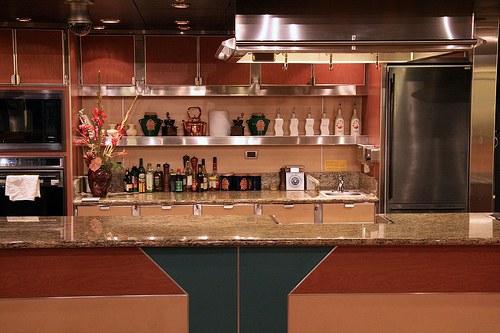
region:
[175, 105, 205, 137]
Gold teapot on shelf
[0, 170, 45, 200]
white kitchen towel on oven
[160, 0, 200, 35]
recessed lighting in ceiling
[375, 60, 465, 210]
stainless steel refridgerator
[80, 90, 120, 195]
vase full of flowers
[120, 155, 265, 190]
condiments lined up on counter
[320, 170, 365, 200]
silver kitchen sink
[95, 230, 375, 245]
reflection of light on counter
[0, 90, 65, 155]
black kitchen appliance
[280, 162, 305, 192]
white food scale on counter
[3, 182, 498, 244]
A light brown marble countertop.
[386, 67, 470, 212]
A silver refrigerator.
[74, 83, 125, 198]
Red flowers on the countertop.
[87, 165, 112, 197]
A brown flower vase.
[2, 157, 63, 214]
A silver and black oven.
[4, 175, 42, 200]
A white dish cloth.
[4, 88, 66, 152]
A silver and black microwave.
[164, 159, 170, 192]
A brown pepper grinder.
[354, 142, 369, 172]
A silver box on the wall with a paper towel hanging out of it.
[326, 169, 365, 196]
A small sink.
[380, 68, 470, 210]
refrigerator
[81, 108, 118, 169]
flowers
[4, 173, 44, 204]
a cloth on the oven door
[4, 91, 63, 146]
the microwave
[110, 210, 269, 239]
a marble counter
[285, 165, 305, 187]
a white food scale on the counter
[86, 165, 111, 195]
a vase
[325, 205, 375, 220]
drawers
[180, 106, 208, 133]
a brown tea kettle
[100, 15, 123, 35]
a light on the ceiling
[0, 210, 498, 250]
tan-colored kitchen island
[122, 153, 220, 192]
variety of cooking sauces and spices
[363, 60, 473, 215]
stainless steel refrigerator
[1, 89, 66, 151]
black microwave mounted on wall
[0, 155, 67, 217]
black oven with a white towel hanging from it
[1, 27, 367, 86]
cherrywood-colored upper kitchen cabinets with steel trim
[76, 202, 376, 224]
cream color drawers with steel trim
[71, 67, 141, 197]
red flowers in a ceramic vase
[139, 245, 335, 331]
blue front of kitchen island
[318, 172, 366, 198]
small kitchen sink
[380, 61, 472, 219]
Stainless steel refrigerator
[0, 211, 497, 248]
Large kitchen counter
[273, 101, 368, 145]
Row of bottles on a kitchen shelf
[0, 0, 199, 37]
Recessed lights in a ceiling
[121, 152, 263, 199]
Row of cans and bottles on a counter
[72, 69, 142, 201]
Large bouquet of flowers in a vase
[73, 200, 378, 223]
Row of kitchen drawers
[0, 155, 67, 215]
Oven with towel on door handle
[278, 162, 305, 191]
Kitchen scale and pepper mill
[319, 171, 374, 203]
Small sink in kitchen counter